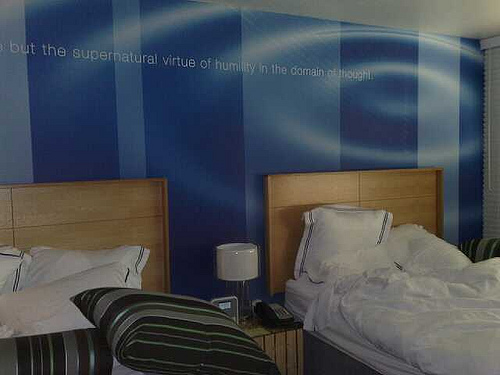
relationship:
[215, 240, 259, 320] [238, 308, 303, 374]
lamp on nightstand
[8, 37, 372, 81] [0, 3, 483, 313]
words on wall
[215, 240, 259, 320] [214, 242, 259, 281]
lamp with white shade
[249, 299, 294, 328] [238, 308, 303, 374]
phone on nightstand